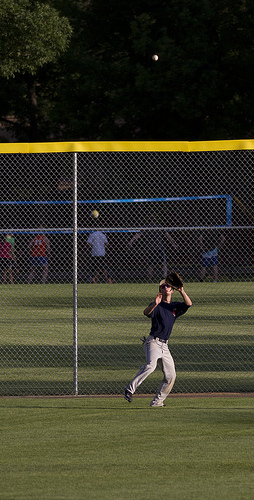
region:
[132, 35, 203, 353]
player trying to catch ball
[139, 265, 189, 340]
player wearing baseball mitt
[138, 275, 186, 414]
player wearing gray pants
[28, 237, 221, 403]
fence and post behind baseball player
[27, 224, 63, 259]
orange and white shirt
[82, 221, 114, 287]
person wearing white shirt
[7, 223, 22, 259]
person wearing green shirt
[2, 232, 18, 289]
person wearing red shirt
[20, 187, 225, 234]
volleyball net and ball behind fence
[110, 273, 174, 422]
player has right foot off ground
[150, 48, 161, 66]
A white ball flying through the air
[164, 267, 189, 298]
a catchers mitt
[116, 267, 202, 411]
A man playing baseball and reaching for the ball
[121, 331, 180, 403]
A man wearing white pants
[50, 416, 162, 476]
the green grass on the field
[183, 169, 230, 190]
a fence in the park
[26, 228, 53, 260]
a man in an orange shirt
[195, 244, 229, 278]
a man in blue shorts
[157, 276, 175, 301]
the face of a man wearing glasses and a cap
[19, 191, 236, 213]
the blue edge of a net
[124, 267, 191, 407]
a baseball player catching a baseball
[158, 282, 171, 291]
the baseball player is wearing sunglasses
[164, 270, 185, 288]
a leather baseball glove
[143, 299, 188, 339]
a black baseball shirt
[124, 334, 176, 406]
grey baseball pants with a blue stripe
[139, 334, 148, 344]
batter gloves in the players pocket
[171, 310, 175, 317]
team logo on the players shirt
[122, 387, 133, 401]
black baseball shoes on the player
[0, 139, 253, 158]
a yellow marker tape on the top of the fence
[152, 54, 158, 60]
a white leather basebal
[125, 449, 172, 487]
The grass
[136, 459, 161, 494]
The grass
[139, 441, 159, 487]
The grass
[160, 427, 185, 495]
The grass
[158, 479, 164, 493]
The grass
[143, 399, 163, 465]
The grass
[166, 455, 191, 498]
The grass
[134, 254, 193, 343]
a glove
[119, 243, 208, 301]
a glove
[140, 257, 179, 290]
a glove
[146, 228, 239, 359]
a glove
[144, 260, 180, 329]
a glove